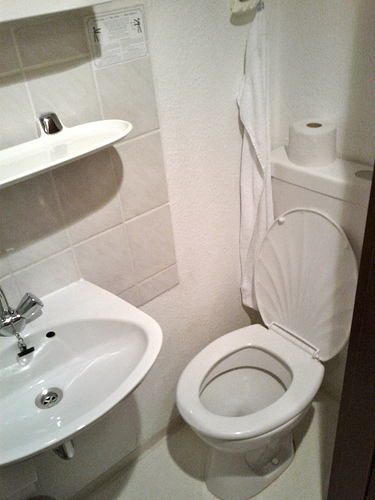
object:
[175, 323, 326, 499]
toilet bowl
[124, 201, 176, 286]
tile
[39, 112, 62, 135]
fixture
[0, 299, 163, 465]
bathroom sink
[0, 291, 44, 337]
bathroom faucet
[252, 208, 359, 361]
lid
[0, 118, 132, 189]
counter shelf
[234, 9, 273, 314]
towel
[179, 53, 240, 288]
wall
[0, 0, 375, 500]
bathroom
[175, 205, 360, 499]
toilet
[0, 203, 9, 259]
wall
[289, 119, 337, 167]
roll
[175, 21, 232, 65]
wall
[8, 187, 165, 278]
bathroom wall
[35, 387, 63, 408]
drain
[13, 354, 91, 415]
sink bottom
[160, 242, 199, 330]
wall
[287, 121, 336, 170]
cover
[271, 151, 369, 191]
top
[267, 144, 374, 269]
tank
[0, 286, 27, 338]
knob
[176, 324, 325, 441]
seat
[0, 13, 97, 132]
wall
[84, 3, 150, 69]
sign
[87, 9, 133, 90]
stick figures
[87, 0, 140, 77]
wall